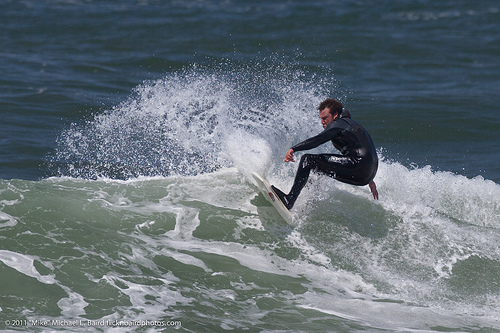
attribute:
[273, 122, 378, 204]
wetsuit — black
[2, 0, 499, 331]
surface — water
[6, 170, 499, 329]
wave — small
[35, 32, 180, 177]
water — green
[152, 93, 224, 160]
water drops — white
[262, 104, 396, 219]
wetsuit — black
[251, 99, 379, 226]
wetsuit — black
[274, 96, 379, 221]
man — crouching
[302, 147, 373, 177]
reflection — light